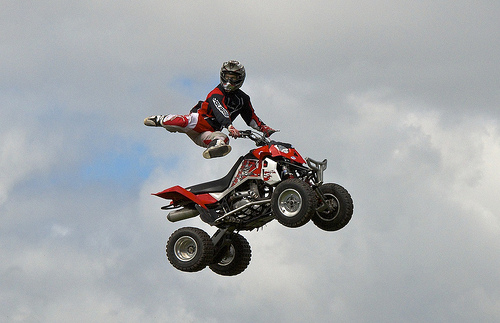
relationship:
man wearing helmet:
[143, 59, 277, 158] [213, 57, 242, 94]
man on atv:
[143, 59, 277, 158] [151, 129, 354, 276]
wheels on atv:
[159, 177, 371, 279] [158, 126, 367, 288]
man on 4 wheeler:
[144, 60, 275, 159] [140, 135, 356, 283]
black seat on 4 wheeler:
[178, 155, 248, 197] [150, 129, 353, 275]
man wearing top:
[144, 60, 275, 159] [201, 87, 251, 124]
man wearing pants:
[143, 59, 277, 158] [146, 104, 230, 158]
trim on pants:
[163, 112, 188, 125] [158, 110, 229, 155]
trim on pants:
[203, 138, 211, 144] [158, 110, 229, 155]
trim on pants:
[221, 136, 231, 143] [158, 110, 229, 155]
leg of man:
[140, 107, 199, 135] [143, 59, 277, 158]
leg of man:
[200, 131, 232, 158] [143, 59, 277, 158]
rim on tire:
[276, 187, 303, 218] [269, 176, 317, 227]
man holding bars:
[144, 60, 275, 159] [222, 113, 274, 148]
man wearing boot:
[143, 59, 277, 158] [201, 142, 233, 159]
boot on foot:
[201, 142, 233, 159] [199, 142, 233, 159]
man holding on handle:
[143, 59, 277, 158] [263, 126, 279, 140]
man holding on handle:
[143, 59, 277, 158] [226, 126, 251, 138]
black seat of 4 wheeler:
[184, 155, 244, 195] [150, 129, 353, 275]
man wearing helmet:
[144, 60, 275, 159] [214, 52, 249, 86]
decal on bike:
[229, 158, 276, 189] [142, 132, 372, 288]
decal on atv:
[232, 158, 274, 188] [151, 129, 354, 276]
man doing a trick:
[144, 60, 275, 159] [134, 46, 364, 307]